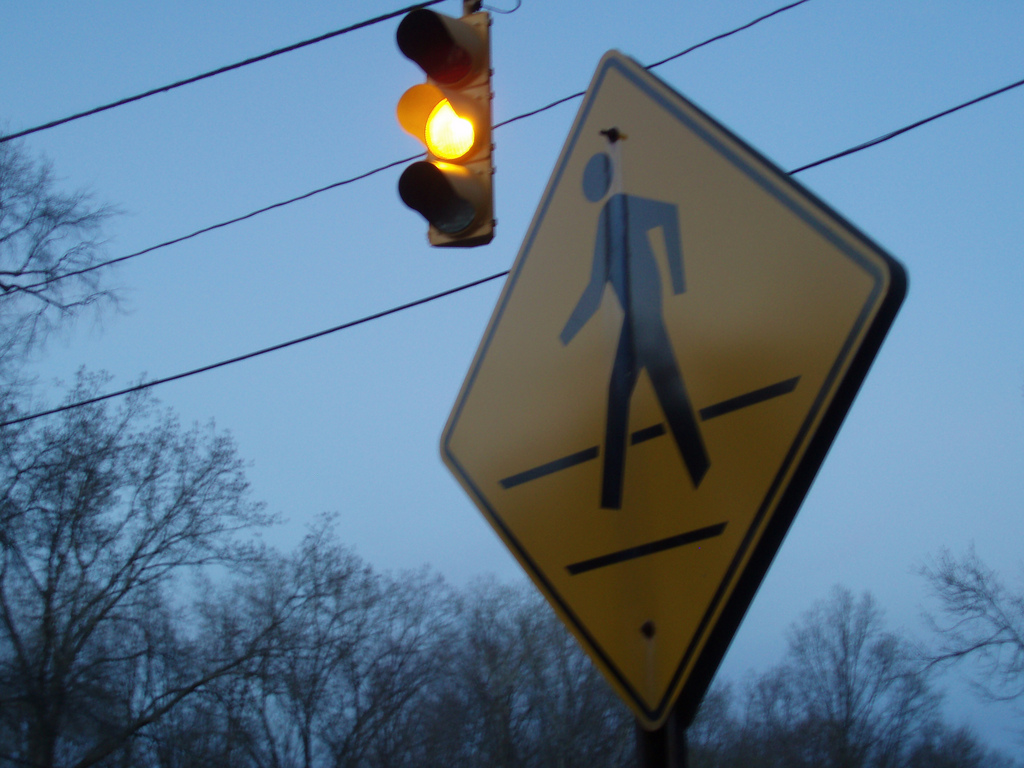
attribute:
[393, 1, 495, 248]
stop light — yellow, ellow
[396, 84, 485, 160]
traffic light — yellow, warig, hagig, working, here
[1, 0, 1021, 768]
sky — gloomy blue, blue, cloudy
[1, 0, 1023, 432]
power lines — here, horizontal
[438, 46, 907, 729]
sign — black bolt, yellow, ellow, diamod shaped, here, diamond shaped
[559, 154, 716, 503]
stick figure ma — here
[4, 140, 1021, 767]
trees — bare, pointy, very tall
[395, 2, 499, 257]
street light — hanging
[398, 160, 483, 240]
gree light — ot lit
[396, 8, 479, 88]
red light — ot lit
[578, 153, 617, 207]
drawig of head — here